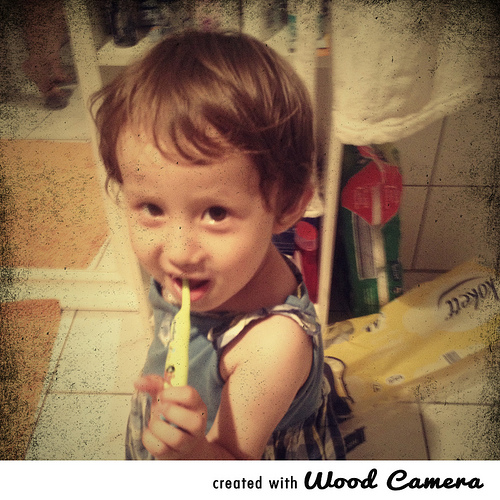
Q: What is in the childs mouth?
A: Toothbrush.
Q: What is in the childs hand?
A: Toothbrush.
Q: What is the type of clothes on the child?
A: A dress.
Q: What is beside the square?
A: A crack in counter tile.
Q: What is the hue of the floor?
A: White and cream.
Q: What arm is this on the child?
A: Left arm.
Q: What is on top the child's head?
A: Brown hair.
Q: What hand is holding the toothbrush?
A: Left hand.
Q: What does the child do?
A: Brushes teeth.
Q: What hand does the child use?
A: The left hand is used to hold toothbrush.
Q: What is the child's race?
A: Caucasian.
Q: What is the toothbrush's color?
A: Yellow.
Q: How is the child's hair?
A: Short and brown.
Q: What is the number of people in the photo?
A: One person.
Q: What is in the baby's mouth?
A: A toothbrush.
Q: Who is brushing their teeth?
A: A baby.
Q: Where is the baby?
A: In the bathroom.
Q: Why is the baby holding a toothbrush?
A: To brush her teeth.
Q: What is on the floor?
A: Rugs.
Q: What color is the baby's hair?
A: Brown.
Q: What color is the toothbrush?
A: Yellow.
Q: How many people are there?
A: One.